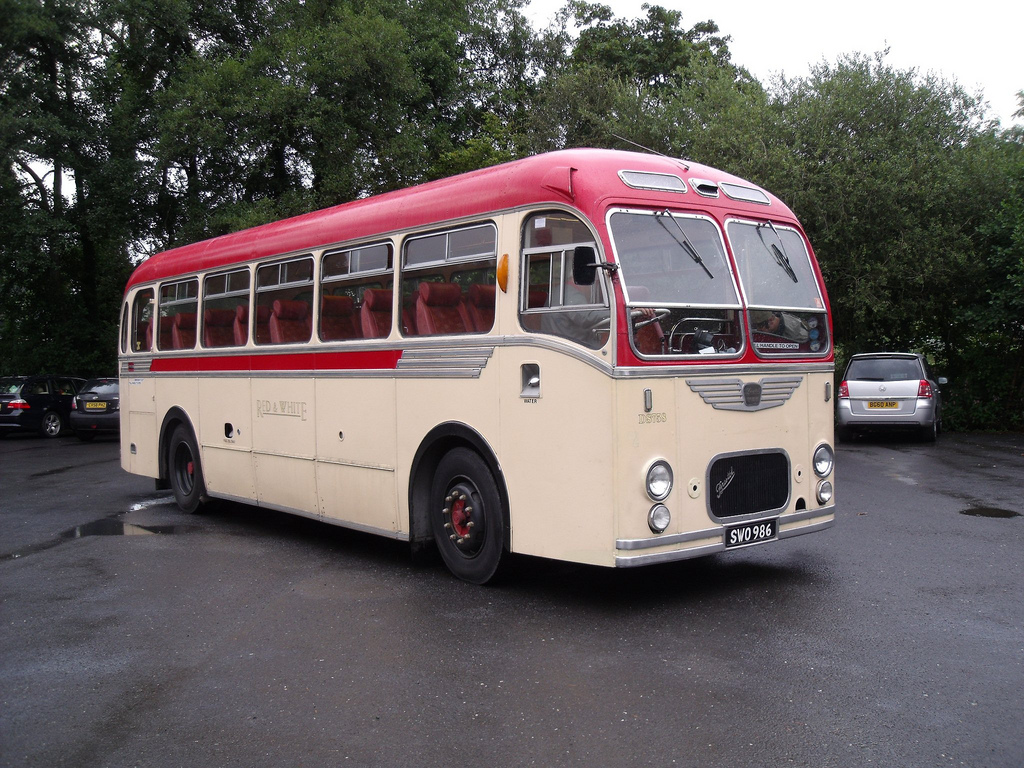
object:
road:
[0, 429, 1024, 768]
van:
[0, 376, 89, 438]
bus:
[117, 133, 834, 585]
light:
[496, 254, 509, 294]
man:
[539, 257, 656, 352]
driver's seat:
[519, 209, 668, 355]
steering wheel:
[586, 308, 671, 333]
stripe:
[149, 350, 402, 371]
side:
[119, 147, 618, 585]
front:
[614, 149, 837, 569]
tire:
[428, 444, 510, 585]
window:
[517, 208, 610, 350]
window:
[605, 207, 747, 360]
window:
[723, 217, 832, 358]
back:
[836, 352, 948, 443]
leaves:
[0, 0, 1024, 426]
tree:
[147, 0, 524, 250]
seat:
[415, 283, 475, 335]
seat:
[466, 283, 495, 334]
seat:
[360, 288, 416, 338]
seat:
[321, 295, 364, 341]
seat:
[269, 298, 313, 343]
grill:
[705, 448, 791, 524]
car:
[69, 378, 123, 441]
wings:
[685, 376, 804, 412]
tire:
[169, 422, 207, 513]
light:
[646, 460, 673, 535]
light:
[812, 444, 834, 506]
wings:
[519, 364, 540, 404]